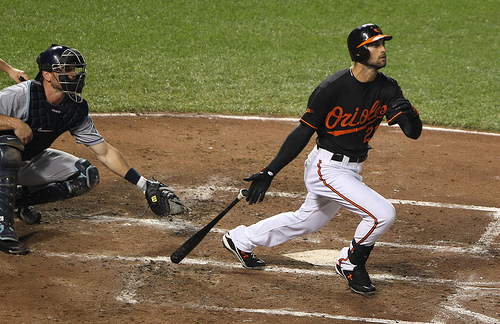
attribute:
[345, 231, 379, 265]
protection — ankle 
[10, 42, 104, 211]
gear —  Nike protection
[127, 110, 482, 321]
box — batter's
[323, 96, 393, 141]
name — team 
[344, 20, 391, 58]
helmet — batting 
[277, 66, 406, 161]
shirt — Orioles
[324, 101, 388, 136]
word — orange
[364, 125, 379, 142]
number — orange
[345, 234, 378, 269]
pad — ankle protection, shin protection gear, knee 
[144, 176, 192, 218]
glove — black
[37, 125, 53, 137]
logo — Nike 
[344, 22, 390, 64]
hat — black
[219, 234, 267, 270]
cleat — black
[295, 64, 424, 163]
jersey — black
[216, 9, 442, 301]
player — baseball 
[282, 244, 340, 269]
home plate — home 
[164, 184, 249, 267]
bat — black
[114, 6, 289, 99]
grass — green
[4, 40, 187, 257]
catcher —  stance for catching.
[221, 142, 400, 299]
pants — white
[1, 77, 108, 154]
shirt — grey